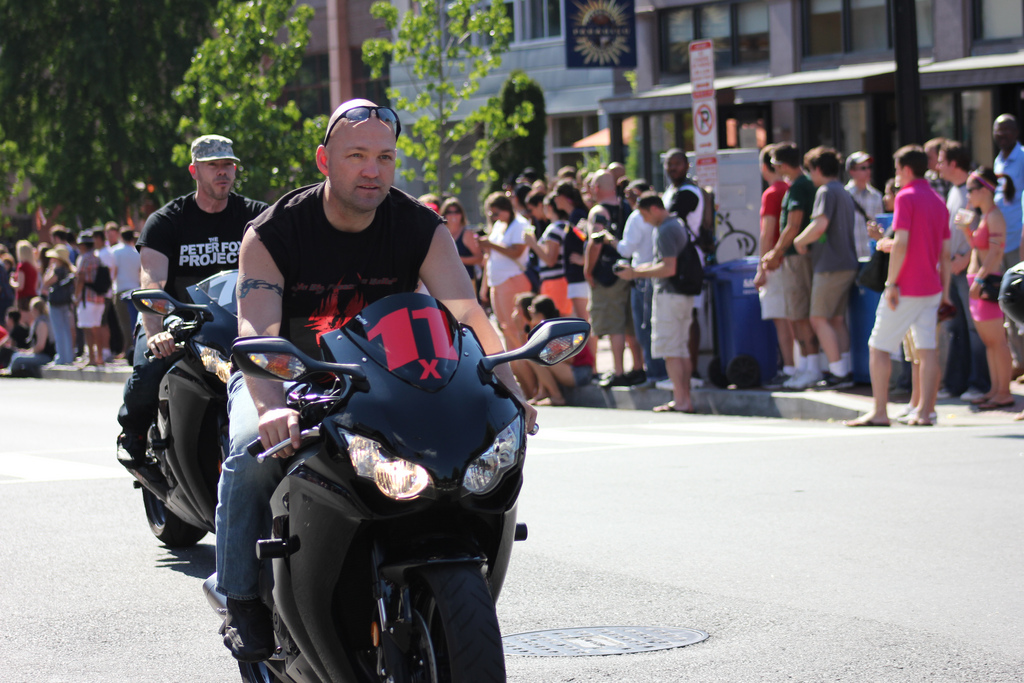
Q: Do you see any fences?
A: No, there are no fences.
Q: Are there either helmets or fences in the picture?
A: No, there are no fences or helmets.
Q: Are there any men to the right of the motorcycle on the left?
A: Yes, there is a man to the right of the motorbike.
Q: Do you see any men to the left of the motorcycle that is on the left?
A: No, the man is to the right of the motorcycle.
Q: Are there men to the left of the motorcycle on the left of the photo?
A: No, the man is to the right of the motorcycle.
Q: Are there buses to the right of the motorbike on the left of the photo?
A: No, there is a man to the right of the motorbike.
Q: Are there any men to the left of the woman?
A: Yes, there is a man to the left of the woman.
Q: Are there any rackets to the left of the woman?
A: No, there is a man to the left of the woman.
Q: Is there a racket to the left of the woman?
A: No, there is a man to the left of the woman.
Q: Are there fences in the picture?
A: No, there are no fences.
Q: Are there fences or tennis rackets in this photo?
A: No, there are no fences or tennis rackets.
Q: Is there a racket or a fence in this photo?
A: No, there are no fences or rackets.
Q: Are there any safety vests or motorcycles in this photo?
A: Yes, there is a motorcycle.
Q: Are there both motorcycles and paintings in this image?
A: No, there is a motorcycle but no paintings.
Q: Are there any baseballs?
A: No, there are no baseballs.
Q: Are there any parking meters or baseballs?
A: No, there are no baseballs or parking meters.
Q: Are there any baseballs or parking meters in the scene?
A: No, there are no baseballs or parking meters.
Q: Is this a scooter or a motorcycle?
A: This is a motorcycle.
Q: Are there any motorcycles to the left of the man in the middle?
A: Yes, there is a motorcycle to the left of the man.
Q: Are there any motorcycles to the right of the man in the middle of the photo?
A: No, the motorcycle is to the left of the man.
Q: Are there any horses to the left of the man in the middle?
A: No, there is a motorcycle to the left of the man.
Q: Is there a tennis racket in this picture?
A: No, there are no rackets.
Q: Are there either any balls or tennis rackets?
A: No, there are no tennis rackets or balls.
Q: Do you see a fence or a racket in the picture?
A: No, there are no fences or rackets.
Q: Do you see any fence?
A: No, there are no fences.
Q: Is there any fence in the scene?
A: No, there are no fences.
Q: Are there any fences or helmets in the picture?
A: No, there are no fences or helmets.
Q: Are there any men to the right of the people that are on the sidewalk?
A: Yes, there is a man to the right of the people.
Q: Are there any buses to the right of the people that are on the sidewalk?
A: No, there is a man to the right of the people.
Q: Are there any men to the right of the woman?
A: Yes, there is a man to the right of the woman.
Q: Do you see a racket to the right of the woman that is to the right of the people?
A: No, there is a man to the right of the woman.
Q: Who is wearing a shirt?
A: The man is wearing a shirt.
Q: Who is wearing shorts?
A: The man is wearing shorts.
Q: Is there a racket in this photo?
A: No, there are no rackets.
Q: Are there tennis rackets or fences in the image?
A: No, there are no tennis rackets or fences.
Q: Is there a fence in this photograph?
A: No, there are no fences.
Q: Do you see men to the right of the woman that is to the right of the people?
A: Yes, there is a man to the right of the woman.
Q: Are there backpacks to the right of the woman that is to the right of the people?
A: No, there is a man to the right of the woman.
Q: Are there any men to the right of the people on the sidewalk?
A: Yes, there is a man to the right of the people.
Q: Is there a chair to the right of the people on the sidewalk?
A: No, there is a man to the right of the people.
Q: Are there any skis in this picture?
A: No, there are no skis.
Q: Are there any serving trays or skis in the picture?
A: No, there are no skis or serving trays.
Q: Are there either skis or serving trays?
A: No, there are no skis or serving trays.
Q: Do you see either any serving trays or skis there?
A: No, there are no skis or serving trays.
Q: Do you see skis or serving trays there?
A: No, there are no skis or serving trays.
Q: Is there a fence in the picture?
A: No, there are no fences.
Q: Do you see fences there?
A: No, there are no fences.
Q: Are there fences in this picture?
A: No, there are no fences.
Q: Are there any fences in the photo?
A: No, there are no fences.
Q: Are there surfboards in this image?
A: No, there are no surfboards.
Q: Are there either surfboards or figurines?
A: No, there are no surfboards or figurines.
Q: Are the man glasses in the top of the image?
A: Yes, the glasses are in the top of the image.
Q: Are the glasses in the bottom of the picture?
A: No, the glasses are in the top of the image.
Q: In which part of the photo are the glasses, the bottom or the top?
A: The glasses are in the top of the image.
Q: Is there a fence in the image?
A: No, there are no fences.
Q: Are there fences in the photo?
A: No, there are no fences.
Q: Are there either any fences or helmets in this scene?
A: No, there are no fences or helmets.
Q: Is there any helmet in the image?
A: No, there are no helmets.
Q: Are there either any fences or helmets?
A: No, there are no helmets or fences.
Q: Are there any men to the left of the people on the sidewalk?
A: Yes, there is a man to the left of the people.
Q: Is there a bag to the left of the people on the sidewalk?
A: No, there is a man to the left of the people.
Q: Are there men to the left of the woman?
A: Yes, there is a man to the left of the woman.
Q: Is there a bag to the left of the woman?
A: No, there is a man to the left of the woman.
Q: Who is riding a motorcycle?
A: The man is riding a motorcycle.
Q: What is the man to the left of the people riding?
A: The man is riding a motorcycle.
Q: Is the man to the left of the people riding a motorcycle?
A: Yes, the man is riding a motorcycle.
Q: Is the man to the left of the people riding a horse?
A: No, the man is riding a motorcycle.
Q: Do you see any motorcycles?
A: Yes, there is a motorcycle.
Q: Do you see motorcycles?
A: Yes, there is a motorcycle.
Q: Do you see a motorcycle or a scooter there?
A: Yes, there is a motorcycle.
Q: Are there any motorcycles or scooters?
A: Yes, there is a motorcycle.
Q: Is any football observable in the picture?
A: No, there are no footballs.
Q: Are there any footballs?
A: No, there are no footballs.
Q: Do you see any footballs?
A: No, there are no footballs.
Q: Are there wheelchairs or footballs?
A: No, there are no footballs or wheelchairs.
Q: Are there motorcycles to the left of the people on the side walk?
A: Yes, there is a motorcycle to the left of the people.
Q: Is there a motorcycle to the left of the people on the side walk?
A: Yes, there is a motorcycle to the left of the people.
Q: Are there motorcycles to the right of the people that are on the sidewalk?
A: No, the motorcycle is to the left of the people.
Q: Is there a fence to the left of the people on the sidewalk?
A: No, there is a motorcycle to the left of the people.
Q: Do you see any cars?
A: No, there are no cars.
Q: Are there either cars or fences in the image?
A: No, there are no cars or fences.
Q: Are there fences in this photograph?
A: No, there are no fences.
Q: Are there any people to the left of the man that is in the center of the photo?
A: Yes, there are people to the left of the man.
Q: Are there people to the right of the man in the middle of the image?
A: No, the people are to the left of the man.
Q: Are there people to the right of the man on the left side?
A: Yes, there are people to the right of the man.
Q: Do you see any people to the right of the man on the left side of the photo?
A: Yes, there are people to the right of the man.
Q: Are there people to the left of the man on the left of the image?
A: No, the people are to the right of the man.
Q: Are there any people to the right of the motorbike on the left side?
A: Yes, there are people to the right of the motorbike.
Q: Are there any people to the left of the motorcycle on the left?
A: No, the people are to the right of the motorbike.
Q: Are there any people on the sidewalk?
A: Yes, there are people on the sidewalk.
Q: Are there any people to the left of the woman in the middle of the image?
A: Yes, there are people to the left of the woman.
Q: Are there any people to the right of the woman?
A: No, the people are to the left of the woman.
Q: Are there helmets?
A: No, there are no helmets.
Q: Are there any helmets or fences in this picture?
A: No, there are no helmets or fences.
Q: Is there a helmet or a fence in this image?
A: No, there are no helmets or fences.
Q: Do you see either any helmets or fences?
A: No, there are no helmets or fences.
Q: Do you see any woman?
A: Yes, there is a woman.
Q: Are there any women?
A: Yes, there is a woman.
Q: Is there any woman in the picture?
A: Yes, there is a woman.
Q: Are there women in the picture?
A: Yes, there is a woman.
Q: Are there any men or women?
A: Yes, there is a woman.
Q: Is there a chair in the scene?
A: No, there are no chairs.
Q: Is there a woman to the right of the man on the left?
A: Yes, there is a woman to the right of the man.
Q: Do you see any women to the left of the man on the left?
A: No, the woman is to the right of the man.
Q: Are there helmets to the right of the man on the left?
A: No, there is a woman to the right of the man.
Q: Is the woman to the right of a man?
A: Yes, the woman is to the right of a man.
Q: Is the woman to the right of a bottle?
A: No, the woman is to the right of a man.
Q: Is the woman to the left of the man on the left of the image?
A: No, the woman is to the right of the man.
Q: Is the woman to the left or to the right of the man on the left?
A: The woman is to the right of the man.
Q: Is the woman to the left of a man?
A: Yes, the woman is to the left of a man.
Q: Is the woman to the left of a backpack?
A: No, the woman is to the left of a man.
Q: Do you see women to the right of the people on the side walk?
A: Yes, there is a woman to the right of the people.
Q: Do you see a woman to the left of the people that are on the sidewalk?
A: No, the woman is to the right of the people.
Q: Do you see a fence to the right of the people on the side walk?
A: No, there is a woman to the right of the people.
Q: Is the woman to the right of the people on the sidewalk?
A: Yes, the woman is to the right of the people.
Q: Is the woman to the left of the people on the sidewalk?
A: No, the woman is to the right of the people.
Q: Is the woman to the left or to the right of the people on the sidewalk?
A: The woman is to the right of the people.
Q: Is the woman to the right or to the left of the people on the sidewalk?
A: The woman is to the right of the people.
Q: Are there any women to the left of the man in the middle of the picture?
A: Yes, there is a woman to the left of the man.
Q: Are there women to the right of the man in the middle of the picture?
A: No, the woman is to the left of the man.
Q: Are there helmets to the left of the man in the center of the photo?
A: No, there is a woman to the left of the man.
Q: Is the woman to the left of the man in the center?
A: Yes, the woman is to the left of the man.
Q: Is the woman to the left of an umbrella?
A: No, the woman is to the left of the man.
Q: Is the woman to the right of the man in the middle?
A: No, the woman is to the left of the man.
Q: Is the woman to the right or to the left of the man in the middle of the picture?
A: The woman is to the left of the man.